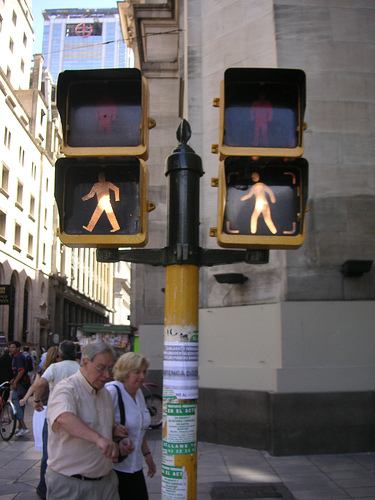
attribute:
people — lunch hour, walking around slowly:
[44, 341, 155, 498]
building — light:
[186, 5, 374, 65]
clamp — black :
[154, 235, 209, 271]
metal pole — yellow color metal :
[156, 129, 214, 251]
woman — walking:
[106, 343, 159, 498]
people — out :
[17, 328, 152, 480]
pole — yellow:
[146, 260, 218, 468]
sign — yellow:
[54, 69, 157, 247]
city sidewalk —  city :
[208, 443, 277, 484]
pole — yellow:
[158, 264, 200, 499]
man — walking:
[42, 339, 122, 499]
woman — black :
[107, 351, 157, 498]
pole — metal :
[163, 116, 203, 499]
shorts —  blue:
[9, 378, 32, 420]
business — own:
[0, 325, 156, 492]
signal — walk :
[54, 149, 303, 243]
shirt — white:
[102, 378, 150, 472]